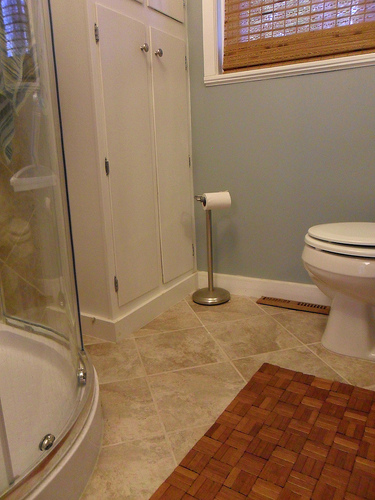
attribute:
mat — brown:
[147, 360, 374, 498]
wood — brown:
[148, 362, 373, 499]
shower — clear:
[1, 9, 100, 497]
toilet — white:
[301, 221, 373, 360]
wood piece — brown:
[321, 394, 341, 414]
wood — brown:
[293, 402, 319, 422]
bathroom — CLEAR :
[0, 7, 107, 469]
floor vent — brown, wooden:
[254, 295, 332, 316]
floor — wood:
[20, 289, 373, 499]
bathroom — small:
[1, 1, 374, 499]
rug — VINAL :
[144, 361, 373, 499]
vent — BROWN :
[254, 292, 331, 318]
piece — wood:
[146, 361, 374, 498]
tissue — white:
[200, 190, 232, 211]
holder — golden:
[189, 188, 232, 305]